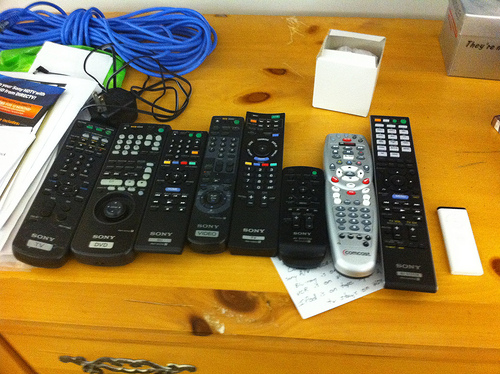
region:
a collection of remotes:
[13, 113, 484, 293]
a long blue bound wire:
[1, 5, 216, 75]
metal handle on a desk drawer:
[57, 354, 190, 372]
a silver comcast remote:
[324, 131, 379, 274]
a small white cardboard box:
[315, 26, 383, 117]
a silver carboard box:
[443, 0, 498, 81]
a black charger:
[79, 48, 189, 122]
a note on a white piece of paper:
[270, 251, 395, 319]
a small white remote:
[435, 206, 485, 278]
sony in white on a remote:
[90, 233, 116, 239]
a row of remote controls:
[44, 37, 489, 316]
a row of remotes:
[16, 65, 460, 329]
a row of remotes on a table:
[18, 66, 476, 318]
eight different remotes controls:
[23, 64, 461, 295]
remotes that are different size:
[44, 82, 455, 324]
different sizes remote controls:
[35, 90, 418, 360]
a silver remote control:
[309, 100, 391, 285]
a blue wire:
[2, 0, 221, 100]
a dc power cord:
[62, 28, 207, 157]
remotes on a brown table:
[14, 78, 497, 303]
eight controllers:
[70, 121, 427, 268]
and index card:
[268, 272, 346, 305]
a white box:
[304, 33, 403, 107]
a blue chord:
[89, 12, 197, 47]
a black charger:
[88, 87, 174, 112]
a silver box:
[440, 15, 495, 75]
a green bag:
[2, 50, 22, 73]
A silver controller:
[320, 127, 375, 277]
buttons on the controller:
[115, 125, 155, 150]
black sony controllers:
[27, 207, 264, 248]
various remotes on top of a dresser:
[15, 110, 439, 290]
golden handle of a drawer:
[55, 345, 200, 371]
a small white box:
[312, 16, 382, 111]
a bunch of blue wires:
[1, 0, 212, 66]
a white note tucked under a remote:
[265, 251, 390, 316]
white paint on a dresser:
[197, 301, 242, 337]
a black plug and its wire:
[80, 50, 200, 121]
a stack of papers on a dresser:
[3, 66, 58, 324]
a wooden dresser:
[6, 275, 259, 371]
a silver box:
[435, 3, 497, 90]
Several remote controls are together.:
[5, 90, 466, 307]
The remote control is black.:
[370, 105, 436, 300]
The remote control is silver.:
[309, 127, 384, 284]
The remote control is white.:
[425, 191, 490, 281]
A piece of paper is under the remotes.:
[256, 225, 398, 334]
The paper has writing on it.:
[266, 227, 386, 330]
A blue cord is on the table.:
[0, 3, 217, 68]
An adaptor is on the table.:
[70, 36, 207, 136]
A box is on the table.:
[290, 18, 396, 132]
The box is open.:
[290, 16, 410, 127]